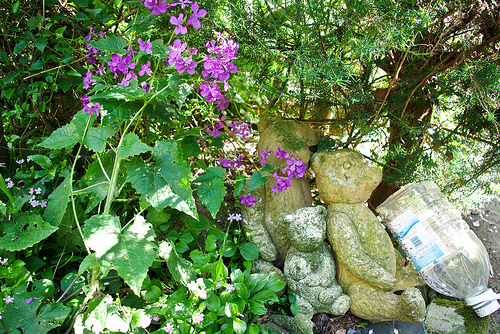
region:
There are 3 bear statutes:
[255, 125, 400, 324]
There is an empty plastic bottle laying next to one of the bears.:
[387, 147, 494, 307]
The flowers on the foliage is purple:
[65, 0, 314, 217]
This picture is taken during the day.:
[0, 0, 497, 318]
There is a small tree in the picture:
[344, 3, 496, 139]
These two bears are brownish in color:
[255, 88, 383, 206]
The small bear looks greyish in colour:
[285, 201, 368, 326]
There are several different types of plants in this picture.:
[12, 124, 284, 328]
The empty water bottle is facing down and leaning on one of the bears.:
[322, 69, 497, 313]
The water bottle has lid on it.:
[382, 181, 496, 326]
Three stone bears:
[241, 101, 426, 331]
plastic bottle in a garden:
[377, 175, 497, 317]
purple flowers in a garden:
[65, 5, 260, 112]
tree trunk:
[363, 75, 439, 210]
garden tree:
[235, 5, 491, 182]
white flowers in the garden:
[41, 270, 247, 328]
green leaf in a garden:
[71, 207, 164, 293]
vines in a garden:
[0, 8, 81, 120]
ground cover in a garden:
[1, 210, 234, 328]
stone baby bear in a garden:
[279, 199, 349, 331]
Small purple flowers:
[75, 6, 247, 126]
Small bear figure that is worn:
[273, 203, 357, 331]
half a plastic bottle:
[376, 178, 499, 321]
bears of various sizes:
[232, 109, 430, 332]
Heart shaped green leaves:
[28, 108, 216, 310]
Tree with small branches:
[369, 18, 491, 160]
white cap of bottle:
[467, 287, 498, 317]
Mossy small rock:
[414, 287, 495, 332]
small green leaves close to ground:
[181, 263, 288, 325]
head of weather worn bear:
[306, 148, 389, 206]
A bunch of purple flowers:
[122, 13, 263, 117]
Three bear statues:
[236, 107, 420, 321]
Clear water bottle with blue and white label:
[376, 182, 495, 313]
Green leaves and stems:
[45, 115, 184, 253]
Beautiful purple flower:
[200, 42, 239, 107]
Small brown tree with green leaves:
[379, 18, 465, 158]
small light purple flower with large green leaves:
[3, 161, 53, 209]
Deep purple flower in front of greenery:
[197, 33, 259, 92]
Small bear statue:
[278, 200, 351, 325]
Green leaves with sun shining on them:
[78, 205, 185, 329]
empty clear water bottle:
[370, 183, 489, 332]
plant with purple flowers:
[45, 17, 318, 287]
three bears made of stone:
[241, 104, 402, 331]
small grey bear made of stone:
[275, 204, 351, 332]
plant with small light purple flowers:
[5, 149, 53, 331]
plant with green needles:
[256, 14, 491, 154]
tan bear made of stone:
[305, 133, 437, 320]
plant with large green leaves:
[53, 119, 213, 298]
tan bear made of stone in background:
[239, 115, 318, 261]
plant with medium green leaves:
[5, 15, 83, 115]